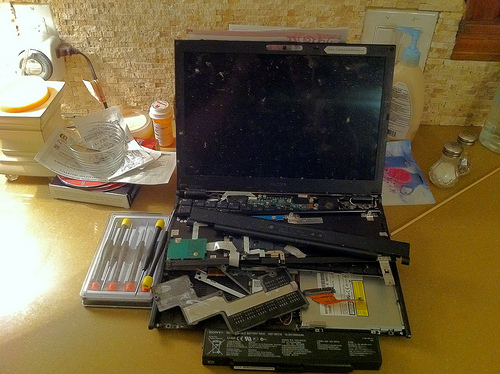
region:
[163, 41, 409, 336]
Torn apart laptop computer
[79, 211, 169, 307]
Box of black, yellow and orange tools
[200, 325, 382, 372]
Black laptop computer battery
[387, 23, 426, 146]
Bottle of lotion with pump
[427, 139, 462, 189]
Glass salt shaker with silver top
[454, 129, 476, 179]
Glass pepper shaker with silver top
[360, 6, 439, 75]
Cream colored light switch on wall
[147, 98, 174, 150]
Orange medicine bottle with white cap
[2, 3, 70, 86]
Electrical outlet plugin on wall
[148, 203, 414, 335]
Computer parts sitting on keyboard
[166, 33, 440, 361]
the laptop on the surface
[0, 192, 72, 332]
light on the surface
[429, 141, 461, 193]
salt shaker on the surface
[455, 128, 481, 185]
the pepper shaker on the surface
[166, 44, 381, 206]
the screen is off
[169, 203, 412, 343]
the laptop is opened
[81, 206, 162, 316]
tools beside the laptop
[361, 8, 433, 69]
the light switch on the wall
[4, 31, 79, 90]
the timer in the outlet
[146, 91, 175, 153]
medicatino on the surface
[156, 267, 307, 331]
a removed computer motherboard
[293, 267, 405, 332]
a computer internal hard drive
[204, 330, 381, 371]
removed laptop internal battery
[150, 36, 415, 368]
an opened laptop computer under repair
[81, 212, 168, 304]
a set of computer screwdrivers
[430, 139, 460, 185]
a glass salt shaker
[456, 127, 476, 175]
a glass pepper shaker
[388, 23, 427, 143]
a pump bottle of soap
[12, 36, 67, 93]
an electronic light timer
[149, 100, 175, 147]
a prescription medicine bottle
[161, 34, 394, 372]
An old black laptop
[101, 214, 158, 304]
A box of tools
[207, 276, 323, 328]
The inside of a computer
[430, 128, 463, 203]
A crystal salt shaker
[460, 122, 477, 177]
A crystal pepper shaker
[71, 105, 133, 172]
A clear glass bowl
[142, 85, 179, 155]
A brown medicine bottle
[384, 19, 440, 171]
A pump bottle of cream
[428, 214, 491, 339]
A yellow counter top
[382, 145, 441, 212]
A paper with pink and blue color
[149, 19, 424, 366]
a laptop sits on the table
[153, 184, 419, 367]
the laptop has been taken apart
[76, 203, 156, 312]
a small kit of tools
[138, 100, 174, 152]
a prescription medication is behind the laptop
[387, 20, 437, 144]
a pump bottle of lotion is on the table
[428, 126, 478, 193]
a salt and pepper shaker is on the table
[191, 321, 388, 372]
the laptops battery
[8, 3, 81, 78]
a few electrical outlets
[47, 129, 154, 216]
a book is on the table behind the laptop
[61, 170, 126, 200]
a few discs are on the book